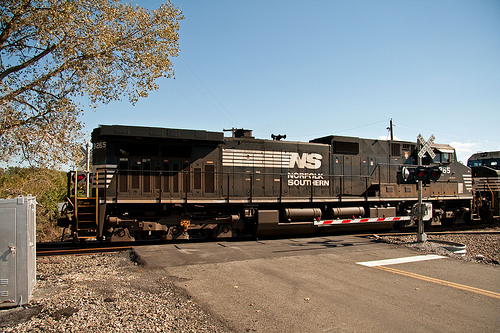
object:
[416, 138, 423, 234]
pole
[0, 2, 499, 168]
sky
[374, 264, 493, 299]
lines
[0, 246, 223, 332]
rocks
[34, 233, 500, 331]
ground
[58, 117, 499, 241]
train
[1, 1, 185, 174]
tree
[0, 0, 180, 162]
leaves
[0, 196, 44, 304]
box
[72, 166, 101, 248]
ladder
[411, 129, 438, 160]
sign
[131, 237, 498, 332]
street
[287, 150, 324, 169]
ns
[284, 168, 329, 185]
norfolk southern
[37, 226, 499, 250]
track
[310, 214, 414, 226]
strip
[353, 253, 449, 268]
line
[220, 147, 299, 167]
stripes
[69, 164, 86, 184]
light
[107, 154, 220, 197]
panels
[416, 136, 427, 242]
pole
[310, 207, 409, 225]
gate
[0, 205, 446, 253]
road crossing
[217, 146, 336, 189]
logo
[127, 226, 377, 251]
ramp